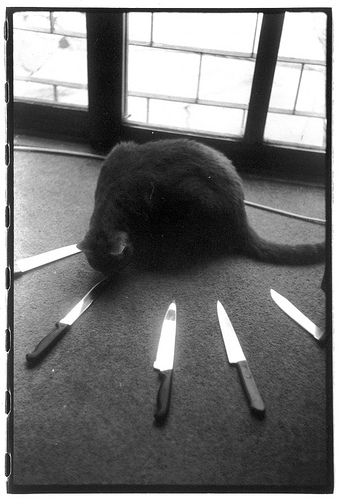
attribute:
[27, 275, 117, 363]
knife — long, shiny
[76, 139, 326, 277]
cat — grey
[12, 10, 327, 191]
window — glass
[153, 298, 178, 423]
knife — shiny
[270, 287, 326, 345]
knife — sharp, silver, shiny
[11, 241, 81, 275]
knife — shiny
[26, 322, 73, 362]
handle — black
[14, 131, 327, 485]
floor — carpeted